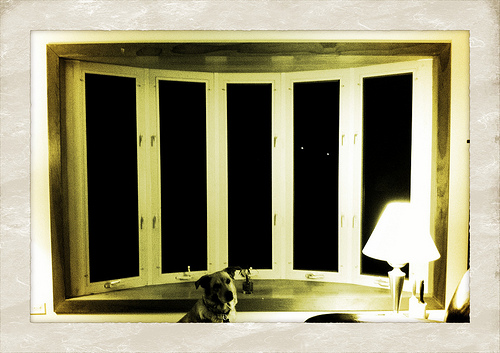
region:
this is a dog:
[189, 269, 233, 326]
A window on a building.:
[85, 67, 139, 284]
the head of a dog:
[189, 262, 248, 309]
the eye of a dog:
[222, 276, 234, 285]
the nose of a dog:
[221, 286, 237, 304]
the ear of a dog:
[188, 272, 205, 292]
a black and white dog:
[173, 260, 246, 324]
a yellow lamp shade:
[357, 195, 447, 267]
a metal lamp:
[383, 265, 411, 315]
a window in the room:
[218, 76, 282, 273]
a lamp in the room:
[363, 195, 444, 314]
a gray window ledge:
[56, 270, 428, 314]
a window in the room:
[151, 68, 217, 275]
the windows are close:
[97, 94, 380, 350]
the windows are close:
[103, 106, 285, 272]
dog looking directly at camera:
[187, 268, 260, 330]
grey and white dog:
[170, 263, 270, 333]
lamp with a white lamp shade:
[360, 198, 442, 322]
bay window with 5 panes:
[82, 55, 461, 286]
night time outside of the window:
[97, 112, 403, 251]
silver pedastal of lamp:
[385, 263, 411, 309]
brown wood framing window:
[43, 38, 78, 108]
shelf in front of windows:
[126, 263, 386, 309]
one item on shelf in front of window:
[235, 258, 273, 297]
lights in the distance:
[297, 136, 354, 170]